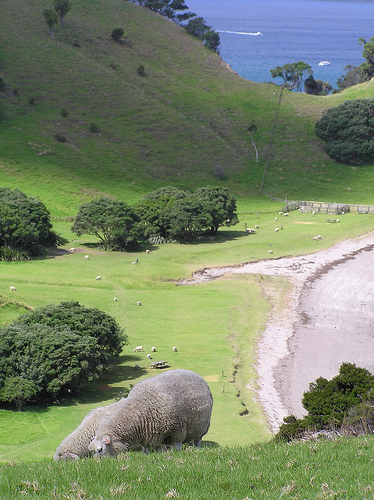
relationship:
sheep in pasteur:
[92, 273, 107, 284] [10, 239, 294, 373]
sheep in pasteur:
[5, 283, 19, 294] [4, 253, 278, 368]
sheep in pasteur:
[131, 343, 144, 352] [6, 254, 301, 385]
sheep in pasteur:
[170, 344, 183, 356] [9, 248, 304, 398]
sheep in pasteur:
[143, 351, 156, 362] [9, 248, 304, 398]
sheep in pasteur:
[148, 345, 161, 354] [9, 248, 304, 398]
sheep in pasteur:
[87, 364, 217, 459] [9, 255, 314, 498]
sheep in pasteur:
[53, 397, 126, 460] [9, 255, 314, 498]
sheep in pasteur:
[240, 224, 257, 237] [7, 151, 362, 469]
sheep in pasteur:
[331, 216, 345, 224] [7, 151, 362, 469]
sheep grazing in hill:
[87, 364, 217, 459] [0, 424, 374, 498]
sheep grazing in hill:
[51, 394, 126, 459] [0, 424, 374, 498]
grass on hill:
[186, 447, 356, 481] [9, 424, 368, 498]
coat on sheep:
[123, 390, 200, 437] [87, 364, 217, 459]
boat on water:
[257, 30, 262, 35] [205, 4, 356, 91]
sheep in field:
[293, 201, 364, 218] [169, 137, 373, 285]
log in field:
[248, 137, 264, 165] [8, 21, 367, 288]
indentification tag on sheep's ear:
[101, 433, 111, 442] [95, 427, 120, 447]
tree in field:
[4, 179, 61, 262] [11, 52, 331, 337]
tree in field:
[69, 194, 158, 252] [11, 52, 331, 337]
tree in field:
[159, 193, 213, 242] [11, 52, 331, 337]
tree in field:
[191, 183, 243, 229] [11, 52, 331, 337]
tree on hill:
[285, 363, 371, 441] [2, 439, 369, 496]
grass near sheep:
[216, 447, 356, 488] [87, 364, 217, 459]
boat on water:
[252, 28, 269, 38] [212, 4, 365, 91]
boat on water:
[315, 54, 337, 72] [212, 4, 365, 91]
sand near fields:
[285, 256, 363, 392] [6, 212, 355, 460]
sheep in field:
[67, 244, 77, 256] [1, 205, 366, 283]